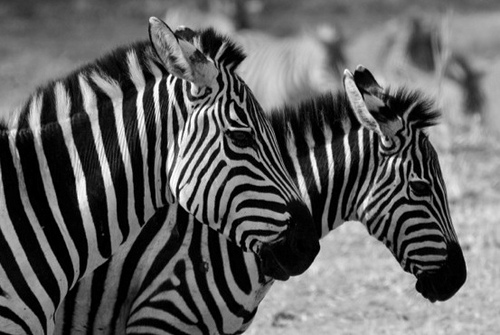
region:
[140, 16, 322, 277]
head of the bigger zebra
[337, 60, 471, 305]
head of the smaller zebra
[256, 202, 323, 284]
muzzle of the bigger zebra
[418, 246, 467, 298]
muzzle of the smaller zebra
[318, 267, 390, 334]
grass below the smaller zebras neck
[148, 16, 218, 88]
right ear of the bigger zebra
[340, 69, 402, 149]
right ear of the smaller zebra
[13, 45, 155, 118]
mane on the bigger zebra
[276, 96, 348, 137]
mane on the smaller zebra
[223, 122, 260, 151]
right eye on the bigger zebra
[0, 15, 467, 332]
a pair of zebras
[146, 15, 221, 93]
the ear of a zebra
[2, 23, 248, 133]
the black and white mane of a zebra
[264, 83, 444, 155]
the black and white mane of a zebra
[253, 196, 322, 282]
the black mouth of a zebra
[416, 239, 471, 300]
the black mouth of a zebra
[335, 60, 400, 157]
a pair of zebra ears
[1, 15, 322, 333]
a zebra facing the right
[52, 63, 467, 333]
a zebra facing the right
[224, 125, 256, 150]
the eye of a zebra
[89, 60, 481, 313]
the two zebras standing next to each other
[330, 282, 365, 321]
the grass on the ground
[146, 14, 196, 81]
the ears of the zebra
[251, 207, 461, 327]
the noses of the zebra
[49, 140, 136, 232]
the zebras black and whtie stripes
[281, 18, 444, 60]
blurry zebras in the back ground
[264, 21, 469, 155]
the ears of the zebra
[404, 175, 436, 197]
one of the eyes of the zebra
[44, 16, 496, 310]
a scene with zebras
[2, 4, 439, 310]
a black and white photo of animals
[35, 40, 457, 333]
these are some zebras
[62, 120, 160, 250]
the fur is black and white in color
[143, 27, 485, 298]
these are the zebras' heads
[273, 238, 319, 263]
the mouth area is black in color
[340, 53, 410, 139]
these are the ears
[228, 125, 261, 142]
this is the eye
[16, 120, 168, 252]
this is the neck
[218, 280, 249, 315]
this is the chest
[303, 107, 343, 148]
this is some hair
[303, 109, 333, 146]
the hair is raised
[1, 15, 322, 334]
Larger zebra to left of smaller zebra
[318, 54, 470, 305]
Smaller zebra's head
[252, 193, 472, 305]
Black zebra noses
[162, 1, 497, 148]
More zebras in blurry background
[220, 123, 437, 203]
Each zebra has one eye showing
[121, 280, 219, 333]
Top of zebra's leg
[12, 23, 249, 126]
Zebra mane has stripes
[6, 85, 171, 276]
Larger zebra's neck has stripes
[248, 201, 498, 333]
Grass on the ground is grey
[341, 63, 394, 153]
Zebra's ear is pointing backwards